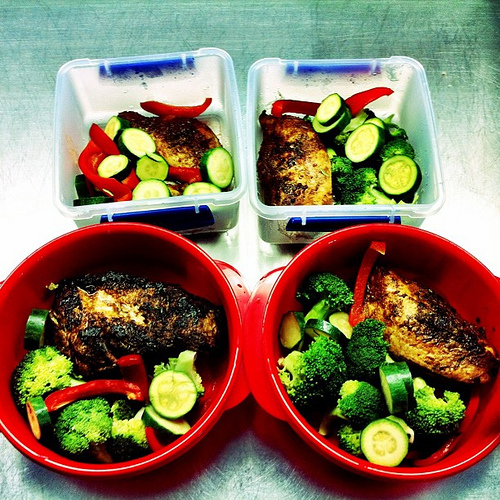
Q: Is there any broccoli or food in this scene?
A: Yes, there is broccoli.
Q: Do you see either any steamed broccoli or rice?
A: Yes, there is steamed broccoli.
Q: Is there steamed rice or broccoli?
A: Yes, there is steamed broccoli.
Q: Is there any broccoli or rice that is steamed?
A: Yes, the broccoli is steamed.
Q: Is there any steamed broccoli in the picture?
A: Yes, there is steamed broccoli.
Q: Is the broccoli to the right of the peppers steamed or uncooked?
A: The broccoli is steamed.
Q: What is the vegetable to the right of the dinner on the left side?
A: The vegetable is broccoli.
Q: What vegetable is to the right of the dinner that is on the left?
A: The vegetable is broccoli.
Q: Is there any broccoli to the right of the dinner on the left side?
A: Yes, there is broccoli to the right of the dinner.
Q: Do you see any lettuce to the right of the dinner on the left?
A: No, there is broccoli to the right of the dinner.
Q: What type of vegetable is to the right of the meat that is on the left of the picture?
A: The vegetable is broccoli.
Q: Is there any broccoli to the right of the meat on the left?
A: Yes, there is broccoli to the right of the meat.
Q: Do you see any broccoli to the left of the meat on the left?
A: No, the broccoli is to the right of the meat.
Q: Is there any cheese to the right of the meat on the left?
A: No, there is broccoli to the right of the meat.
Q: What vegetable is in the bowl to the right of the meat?
A: The vegetable is broccoli.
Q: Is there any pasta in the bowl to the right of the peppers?
A: No, there is broccoli in the bowl.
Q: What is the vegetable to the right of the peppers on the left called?
A: The vegetable is broccoli.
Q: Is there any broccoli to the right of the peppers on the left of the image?
A: Yes, there is broccoli to the right of the peppers.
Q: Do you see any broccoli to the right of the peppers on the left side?
A: Yes, there is broccoli to the right of the peppers.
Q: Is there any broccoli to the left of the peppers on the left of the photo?
A: No, the broccoli is to the right of the peppers.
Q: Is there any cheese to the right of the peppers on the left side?
A: No, there is broccoli to the right of the peppers.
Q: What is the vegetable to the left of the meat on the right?
A: The vegetable is broccoli.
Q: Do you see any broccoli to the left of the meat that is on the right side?
A: Yes, there is broccoli to the left of the meat.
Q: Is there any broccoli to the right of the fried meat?
A: No, the broccoli is to the left of the meat.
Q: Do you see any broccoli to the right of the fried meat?
A: No, the broccoli is to the left of the meat.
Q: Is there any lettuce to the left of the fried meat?
A: No, there is broccoli to the left of the meat.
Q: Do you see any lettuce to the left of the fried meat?
A: No, there is broccoli to the left of the meat.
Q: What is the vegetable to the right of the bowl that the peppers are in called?
A: The vegetable is broccoli.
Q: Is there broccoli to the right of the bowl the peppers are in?
A: Yes, there is broccoli to the right of the bowl.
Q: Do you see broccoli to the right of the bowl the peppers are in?
A: Yes, there is broccoli to the right of the bowl.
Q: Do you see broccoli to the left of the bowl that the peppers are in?
A: No, the broccoli is to the right of the bowl.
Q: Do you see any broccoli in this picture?
A: Yes, there is broccoli.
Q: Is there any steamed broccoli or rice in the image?
A: Yes, there is steamed broccoli.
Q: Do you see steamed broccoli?
A: Yes, there is steamed broccoli.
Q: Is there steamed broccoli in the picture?
A: Yes, there is steamed broccoli.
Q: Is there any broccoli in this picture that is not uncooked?
A: Yes, there is steamed broccoli.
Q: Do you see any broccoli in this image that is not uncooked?
A: Yes, there is steamed broccoli.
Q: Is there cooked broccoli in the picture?
A: Yes, there is cooked broccoli.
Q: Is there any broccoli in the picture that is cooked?
A: Yes, there is broccoli that is cooked.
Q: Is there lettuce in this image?
A: No, there is no lettuce.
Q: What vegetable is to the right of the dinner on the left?
A: The vegetable is broccoli.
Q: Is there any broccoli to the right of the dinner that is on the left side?
A: Yes, there is broccoli to the right of the dinner.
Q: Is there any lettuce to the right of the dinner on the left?
A: No, there is broccoli to the right of the dinner.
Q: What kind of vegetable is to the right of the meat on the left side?
A: The vegetable is broccoli.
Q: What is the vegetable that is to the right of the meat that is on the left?
A: The vegetable is broccoli.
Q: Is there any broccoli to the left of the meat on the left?
A: No, the broccoli is to the right of the meat.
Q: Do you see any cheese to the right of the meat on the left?
A: No, there is broccoli to the right of the meat.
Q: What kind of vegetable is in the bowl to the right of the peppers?
A: The vegetable is broccoli.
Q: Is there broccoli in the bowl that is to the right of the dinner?
A: Yes, there is broccoli in the bowl.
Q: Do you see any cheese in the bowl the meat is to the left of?
A: No, there is broccoli in the bowl.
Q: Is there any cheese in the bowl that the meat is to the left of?
A: No, there is broccoli in the bowl.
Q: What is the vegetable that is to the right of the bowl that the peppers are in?
A: The vegetable is broccoli.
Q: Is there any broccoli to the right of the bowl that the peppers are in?
A: Yes, there is broccoli to the right of the bowl.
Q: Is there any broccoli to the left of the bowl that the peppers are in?
A: No, the broccoli is to the right of the bowl.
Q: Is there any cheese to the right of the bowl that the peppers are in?
A: No, there is broccoli to the right of the bowl.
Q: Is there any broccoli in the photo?
A: Yes, there is broccoli.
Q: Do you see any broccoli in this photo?
A: Yes, there is broccoli.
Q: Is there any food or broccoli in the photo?
A: Yes, there is broccoli.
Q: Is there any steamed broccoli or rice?
A: Yes, there is steamed broccoli.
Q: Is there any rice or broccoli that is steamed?
A: Yes, the broccoli is steamed.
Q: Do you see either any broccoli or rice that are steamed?
A: Yes, the broccoli is steamed.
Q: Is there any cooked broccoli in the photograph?
A: Yes, there is cooked broccoli.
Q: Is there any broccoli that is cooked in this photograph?
A: Yes, there is cooked broccoli.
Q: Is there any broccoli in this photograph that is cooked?
A: Yes, there is broccoli that is cooked.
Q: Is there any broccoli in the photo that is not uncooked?
A: Yes, there is cooked broccoli.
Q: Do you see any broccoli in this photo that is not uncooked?
A: Yes, there is cooked broccoli.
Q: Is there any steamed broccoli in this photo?
A: Yes, there is steamed broccoli.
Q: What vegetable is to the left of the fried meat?
A: The vegetable is broccoli.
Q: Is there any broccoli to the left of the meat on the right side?
A: Yes, there is broccoli to the left of the meat.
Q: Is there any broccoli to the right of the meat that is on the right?
A: No, the broccoli is to the left of the meat.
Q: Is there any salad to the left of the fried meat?
A: No, there is broccoli to the left of the meat.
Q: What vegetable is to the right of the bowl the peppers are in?
A: The vegetable is broccoli.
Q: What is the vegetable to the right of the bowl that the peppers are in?
A: The vegetable is broccoli.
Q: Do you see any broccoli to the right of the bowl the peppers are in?
A: Yes, there is broccoli to the right of the bowl.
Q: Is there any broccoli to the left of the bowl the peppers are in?
A: No, the broccoli is to the right of the bowl.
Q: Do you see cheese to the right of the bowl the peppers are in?
A: No, there is broccoli to the right of the bowl.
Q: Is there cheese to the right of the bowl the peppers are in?
A: No, there is broccoli to the right of the bowl.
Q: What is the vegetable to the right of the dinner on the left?
A: The vegetable is broccoli.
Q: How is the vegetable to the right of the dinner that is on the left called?
A: The vegetable is broccoli.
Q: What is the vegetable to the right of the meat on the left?
A: The vegetable is broccoli.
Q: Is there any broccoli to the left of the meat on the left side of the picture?
A: No, the broccoli is to the right of the meat.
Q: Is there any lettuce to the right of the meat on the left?
A: No, there is broccoli to the right of the meat.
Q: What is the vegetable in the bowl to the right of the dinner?
A: The vegetable is broccoli.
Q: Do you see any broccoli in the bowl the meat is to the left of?
A: Yes, there is broccoli in the bowl.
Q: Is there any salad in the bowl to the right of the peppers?
A: No, there is broccoli in the bowl.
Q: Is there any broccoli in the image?
A: Yes, there is broccoli.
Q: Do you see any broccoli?
A: Yes, there is broccoli.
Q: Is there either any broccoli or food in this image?
A: Yes, there is broccoli.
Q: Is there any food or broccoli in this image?
A: Yes, there is broccoli.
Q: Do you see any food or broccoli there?
A: Yes, there is broccoli.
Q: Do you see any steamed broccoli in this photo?
A: Yes, there is steamed broccoli.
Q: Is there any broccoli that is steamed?
A: Yes, there is broccoli that is steamed.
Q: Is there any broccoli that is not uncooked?
A: Yes, there is steamed broccoli.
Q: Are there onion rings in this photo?
A: No, there are no onion rings.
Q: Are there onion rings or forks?
A: No, there are no onion rings or forks.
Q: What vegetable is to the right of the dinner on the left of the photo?
A: The vegetable is broccoli.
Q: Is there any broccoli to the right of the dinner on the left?
A: Yes, there is broccoli to the right of the dinner.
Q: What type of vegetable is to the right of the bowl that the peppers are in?
A: The vegetable is broccoli.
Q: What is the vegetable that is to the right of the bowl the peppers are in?
A: The vegetable is broccoli.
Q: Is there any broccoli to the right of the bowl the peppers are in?
A: Yes, there is broccoli to the right of the bowl.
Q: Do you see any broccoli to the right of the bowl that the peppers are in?
A: Yes, there is broccoli to the right of the bowl.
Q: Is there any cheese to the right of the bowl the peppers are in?
A: No, there is broccoli to the right of the bowl.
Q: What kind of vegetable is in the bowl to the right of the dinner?
A: The vegetable is broccoli.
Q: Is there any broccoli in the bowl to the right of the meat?
A: Yes, there is broccoli in the bowl.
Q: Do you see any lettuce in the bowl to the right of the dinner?
A: No, there is broccoli in the bowl.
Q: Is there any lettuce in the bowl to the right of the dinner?
A: No, there is broccoli in the bowl.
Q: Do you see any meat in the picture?
A: Yes, there is meat.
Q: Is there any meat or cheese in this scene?
A: Yes, there is meat.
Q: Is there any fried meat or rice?
A: Yes, there is fried meat.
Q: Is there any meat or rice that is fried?
A: Yes, the meat is fried.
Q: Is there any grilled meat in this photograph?
A: Yes, there is grilled meat.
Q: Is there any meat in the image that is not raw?
A: Yes, there is grilled meat.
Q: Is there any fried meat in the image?
A: Yes, there is fried meat.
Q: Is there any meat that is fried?
A: Yes, there is meat that is fried.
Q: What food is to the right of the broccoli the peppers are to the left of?
A: The food is meat.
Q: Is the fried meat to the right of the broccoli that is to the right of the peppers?
A: Yes, the meat is to the right of the broccoli.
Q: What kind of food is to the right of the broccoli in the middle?
A: The food is meat.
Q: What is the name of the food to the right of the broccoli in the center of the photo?
A: The food is meat.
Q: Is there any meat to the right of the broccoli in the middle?
A: Yes, there is meat to the right of the broccoli.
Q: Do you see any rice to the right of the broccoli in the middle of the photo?
A: No, there is meat to the right of the broccoli.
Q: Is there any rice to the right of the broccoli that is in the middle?
A: No, there is meat to the right of the broccoli.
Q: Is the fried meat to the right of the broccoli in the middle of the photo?
A: Yes, the meat is to the right of the broccoli.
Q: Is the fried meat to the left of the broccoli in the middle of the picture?
A: No, the meat is to the right of the broccoli.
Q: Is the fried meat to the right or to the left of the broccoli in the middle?
A: The meat is to the right of the broccoli.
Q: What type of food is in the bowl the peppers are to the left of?
A: The food is meat.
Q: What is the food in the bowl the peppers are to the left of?
A: The food is meat.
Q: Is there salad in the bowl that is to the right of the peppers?
A: No, there is meat in the bowl.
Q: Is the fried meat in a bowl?
A: Yes, the meat is in a bowl.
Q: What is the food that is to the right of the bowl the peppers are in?
A: The food is meat.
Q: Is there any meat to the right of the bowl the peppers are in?
A: Yes, there is meat to the right of the bowl.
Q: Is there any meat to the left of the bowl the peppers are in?
A: No, the meat is to the right of the bowl.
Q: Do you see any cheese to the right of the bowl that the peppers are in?
A: No, there is meat to the right of the bowl.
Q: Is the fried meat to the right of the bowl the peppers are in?
A: Yes, the meat is to the right of the bowl.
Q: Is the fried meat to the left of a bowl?
A: No, the meat is to the right of a bowl.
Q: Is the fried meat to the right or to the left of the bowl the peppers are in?
A: The meat is to the right of the bowl.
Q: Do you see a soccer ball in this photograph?
A: No, there are no soccer balls.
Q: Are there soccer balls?
A: No, there are no soccer balls.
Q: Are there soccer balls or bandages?
A: No, there are no soccer balls or bandages.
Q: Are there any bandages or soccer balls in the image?
A: No, there are no soccer balls or bandages.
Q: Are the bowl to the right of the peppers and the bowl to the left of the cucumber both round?
A: Yes, both the bowl and the bowl are round.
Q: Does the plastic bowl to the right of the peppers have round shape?
A: Yes, the bowl is round.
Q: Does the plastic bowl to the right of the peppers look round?
A: Yes, the bowl is round.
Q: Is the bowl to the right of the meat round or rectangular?
A: The bowl is round.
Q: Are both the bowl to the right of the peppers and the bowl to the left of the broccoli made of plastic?
A: Yes, both the bowl and the bowl are made of plastic.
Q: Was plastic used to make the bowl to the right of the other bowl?
A: Yes, the bowl is made of plastic.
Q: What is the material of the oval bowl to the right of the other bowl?
A: The bowl is made of plastic.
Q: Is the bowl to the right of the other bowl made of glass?
A: No, the bowl is made of plastic.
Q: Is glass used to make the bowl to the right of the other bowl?
A: No, the bowl is made of plastic.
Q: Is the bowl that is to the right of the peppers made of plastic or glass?
A: The bowl is made of plastic.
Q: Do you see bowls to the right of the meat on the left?
A: Yes, there is a bowl to the right of the meat.